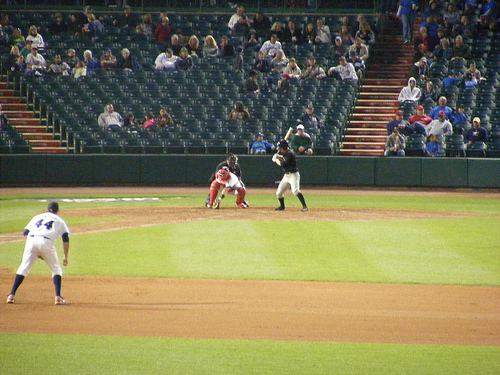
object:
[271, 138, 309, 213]
man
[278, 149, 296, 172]
shirt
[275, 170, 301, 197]
pants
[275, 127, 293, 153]
baseball bat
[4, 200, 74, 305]
man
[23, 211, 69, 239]
shirt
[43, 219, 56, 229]
number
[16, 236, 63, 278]
pants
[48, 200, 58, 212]
cap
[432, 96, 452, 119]
spectator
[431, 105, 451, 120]
shirt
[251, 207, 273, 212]
home plate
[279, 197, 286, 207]
sock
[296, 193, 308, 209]
sock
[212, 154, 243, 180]
umpire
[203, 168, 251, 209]
catcher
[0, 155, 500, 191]
wall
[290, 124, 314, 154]
person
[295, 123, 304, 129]
hat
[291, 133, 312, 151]
shirt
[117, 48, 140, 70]
person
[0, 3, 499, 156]
stands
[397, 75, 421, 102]
person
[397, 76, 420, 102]
hoodie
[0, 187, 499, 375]
baseball field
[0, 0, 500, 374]
stadium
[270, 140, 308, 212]
baseball uniform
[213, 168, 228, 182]
baseball cap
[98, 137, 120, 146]
seat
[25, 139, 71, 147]
stairs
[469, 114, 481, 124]
cap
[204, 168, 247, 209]
safety gear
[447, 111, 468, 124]
jacket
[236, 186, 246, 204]
shinguard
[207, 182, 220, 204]
shinguard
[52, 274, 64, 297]
sock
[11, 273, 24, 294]
sock